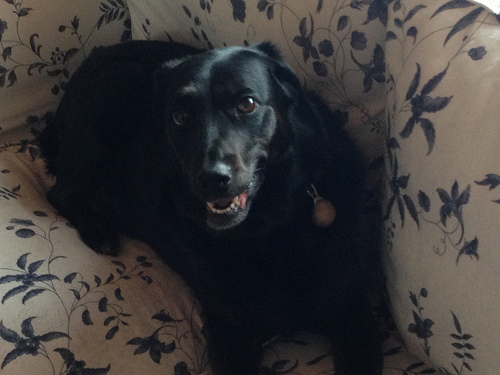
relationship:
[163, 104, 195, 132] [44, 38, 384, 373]
eye on black dog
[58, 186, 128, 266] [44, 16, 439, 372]
paw of dog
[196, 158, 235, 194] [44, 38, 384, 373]
nose on black dog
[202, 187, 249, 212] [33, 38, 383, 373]
teeth on dog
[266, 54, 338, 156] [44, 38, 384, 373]
ear on black dog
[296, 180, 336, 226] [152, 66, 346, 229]
tag on collar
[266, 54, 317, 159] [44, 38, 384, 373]
ear of black dog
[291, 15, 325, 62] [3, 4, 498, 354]
flower on sofa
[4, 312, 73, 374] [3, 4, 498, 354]
flower on sofa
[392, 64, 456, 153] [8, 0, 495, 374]
flower on couch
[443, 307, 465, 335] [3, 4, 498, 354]
leaf on sofa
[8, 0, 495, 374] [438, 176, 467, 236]
couch with floral design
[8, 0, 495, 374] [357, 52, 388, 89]
couch with floral design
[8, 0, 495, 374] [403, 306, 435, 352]
couch with floral design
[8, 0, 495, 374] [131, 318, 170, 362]
couch with floral design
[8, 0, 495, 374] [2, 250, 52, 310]
couch with floral design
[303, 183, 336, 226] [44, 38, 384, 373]
tag on black dog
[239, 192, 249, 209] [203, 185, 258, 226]
gum in mouth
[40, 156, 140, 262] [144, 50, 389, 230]
leg of dog